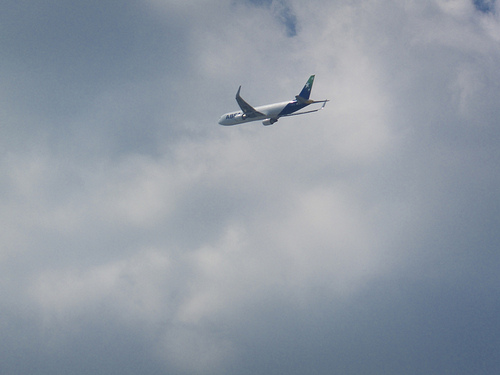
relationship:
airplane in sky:
[218, 73, 330, 126] [2, 1, 499, 373]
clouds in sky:
[0, 0, 499, 374] [2, 1, 499, 373]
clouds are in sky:
[0, 0, 499, 374] [2, 1, 499, 373]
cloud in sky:
[319, 227, 473, 337] [2, 1, 499, 373]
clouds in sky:
[76, 160, 391, 293] [2, 1, 499, 373]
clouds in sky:
[313, 20, 464, 150] [2, 1, 499, 373]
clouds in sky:
[186, 127, 328, 237] [36, 12, 480, 359]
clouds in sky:
[342, 49, 467, 203] [2, 1, 499, 373]